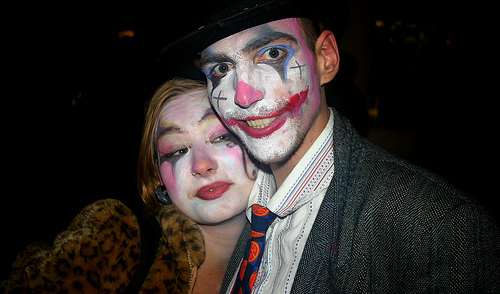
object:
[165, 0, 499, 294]
man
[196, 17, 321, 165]
face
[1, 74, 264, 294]
woman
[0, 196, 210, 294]
coat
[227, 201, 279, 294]
necktie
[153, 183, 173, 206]
earring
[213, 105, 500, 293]
jacket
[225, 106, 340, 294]
shirt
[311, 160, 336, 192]
stripes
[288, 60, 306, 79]
cross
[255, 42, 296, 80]
outline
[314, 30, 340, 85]
ear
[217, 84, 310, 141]
lipstick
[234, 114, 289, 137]
lips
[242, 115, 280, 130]
teeth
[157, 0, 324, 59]
hat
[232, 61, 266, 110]
nose